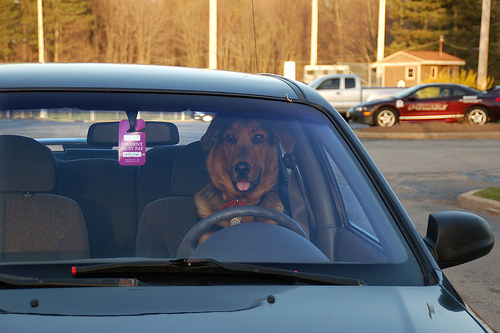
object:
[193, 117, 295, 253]
dog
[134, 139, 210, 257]
seat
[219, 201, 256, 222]
collar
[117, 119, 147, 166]
permit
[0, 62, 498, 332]
car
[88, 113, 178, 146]
mirror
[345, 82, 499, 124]
car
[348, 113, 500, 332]
road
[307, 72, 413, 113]
truck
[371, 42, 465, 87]
house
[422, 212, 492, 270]
mirror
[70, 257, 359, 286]
wiper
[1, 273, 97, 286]
wiper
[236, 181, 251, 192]
toungue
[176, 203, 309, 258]
steering wheel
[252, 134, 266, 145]
eye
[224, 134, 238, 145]
eye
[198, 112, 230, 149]
ear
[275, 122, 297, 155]
ear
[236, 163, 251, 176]
nose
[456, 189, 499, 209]
curb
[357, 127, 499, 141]
curb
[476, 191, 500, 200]
grass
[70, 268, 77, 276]
tip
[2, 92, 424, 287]
windshield